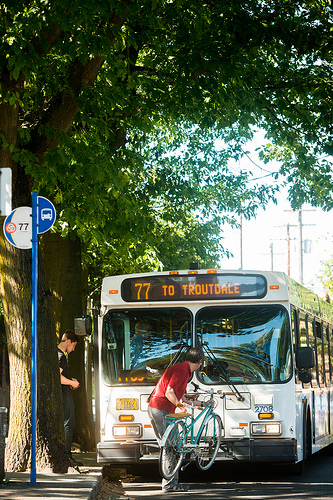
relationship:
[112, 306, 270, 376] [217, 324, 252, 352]
bus windows reflecting light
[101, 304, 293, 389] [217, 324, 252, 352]
bus windows reflecting light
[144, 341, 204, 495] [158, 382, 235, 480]
man putting a bicycle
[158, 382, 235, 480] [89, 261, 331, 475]
bicycle on a bus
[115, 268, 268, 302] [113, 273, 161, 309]
direction light has number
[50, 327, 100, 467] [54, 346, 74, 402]
man wears shirt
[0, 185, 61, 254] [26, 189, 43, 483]
bus signs on pole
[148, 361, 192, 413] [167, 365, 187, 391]
red shirt has sleeve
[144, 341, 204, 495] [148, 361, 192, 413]
man wears red shirt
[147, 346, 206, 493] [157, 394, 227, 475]
man holds bicycle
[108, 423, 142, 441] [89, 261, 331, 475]
headlight on bus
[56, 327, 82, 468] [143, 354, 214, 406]
man wears shirt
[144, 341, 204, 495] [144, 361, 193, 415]
man wears red shirt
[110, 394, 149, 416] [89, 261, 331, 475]
license plate on bus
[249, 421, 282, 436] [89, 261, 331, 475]
headlights on front of bus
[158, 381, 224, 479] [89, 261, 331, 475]
bicycle in front of bus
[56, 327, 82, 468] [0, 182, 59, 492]
man standing at bus stop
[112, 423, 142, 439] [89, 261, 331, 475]
headlight on bus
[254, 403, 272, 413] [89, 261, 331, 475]
id number on front of bus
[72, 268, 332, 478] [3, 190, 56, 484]
bus at bus stop